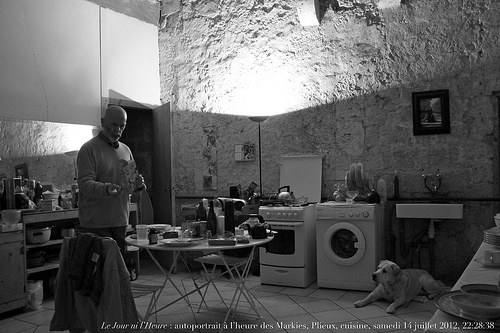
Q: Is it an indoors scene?
A: Yes, it is indoors.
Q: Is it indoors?
A: Yes, it is indoors.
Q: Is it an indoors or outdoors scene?
A: It is indoors.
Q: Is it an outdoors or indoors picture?
A: It is indoors.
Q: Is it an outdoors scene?
A: No, it is indoors.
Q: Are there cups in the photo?
A: No, there are no cups.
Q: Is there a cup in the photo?
A: No, there are no cups.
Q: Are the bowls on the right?
A: Yes, the bowls are on the right of the image.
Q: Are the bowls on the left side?
A: No, the bowls are on the right of the image.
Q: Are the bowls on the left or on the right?
A: The bowls are on the right of the image.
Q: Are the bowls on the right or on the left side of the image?
A: The bowls are on the right of the image.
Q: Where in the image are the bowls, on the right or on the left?
A: The bowls are on the right of the image.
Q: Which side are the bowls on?
A: The bowls are on the right of the image.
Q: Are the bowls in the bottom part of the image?
A: Yes, the bowls are in the bottom of the image.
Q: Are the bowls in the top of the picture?
A: No, the bowls are in the bottom of the image.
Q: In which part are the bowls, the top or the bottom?
A: The bowls are in the bottom of the image.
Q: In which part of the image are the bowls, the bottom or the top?
A: The bowls are in the bottom of the image.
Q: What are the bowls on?
A: The bowls are on the counter top.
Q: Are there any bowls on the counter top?
A: Yes, there are bowls on the counter top.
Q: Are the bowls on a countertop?
A: Yes, the bowls are on a countertop.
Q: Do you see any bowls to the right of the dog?
A: Yes, there are bowls to the right of the dog.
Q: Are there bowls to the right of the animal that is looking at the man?
A: Yes, there are bowls to the right of the dog.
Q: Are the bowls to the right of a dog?
A: Yes, the bowls are to the right of a dog.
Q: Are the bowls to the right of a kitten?
A: No, the bowls are to the right of a dog.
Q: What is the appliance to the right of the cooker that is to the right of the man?
A: The appliance is a washing machine.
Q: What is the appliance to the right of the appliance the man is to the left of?
A: The appliance is a washing machine.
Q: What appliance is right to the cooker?
A: The appliance is a washing machine.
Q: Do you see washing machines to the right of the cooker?
A: Yes, there is a washing machine to the right of the cooker.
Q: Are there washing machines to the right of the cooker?
A: Yes, there is a washing machine to the right of the cooker.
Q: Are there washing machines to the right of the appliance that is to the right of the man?
A: Yes, there is a washing machine to the right of the cooker.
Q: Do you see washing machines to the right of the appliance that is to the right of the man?
A: Yes, there is a washing machine to the right of the cooker.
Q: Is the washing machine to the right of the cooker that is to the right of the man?
A: Yes, the washing machine is to the right of the cooker.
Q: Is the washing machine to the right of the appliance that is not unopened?
A: Yes, the washing machine is to the right of the cooker.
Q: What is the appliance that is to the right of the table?
A: The appliance is a washing machine.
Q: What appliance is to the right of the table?
A: The appliance is a washing machine.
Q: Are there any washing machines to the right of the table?
A: Yes, there is a washing machine to the right of the table.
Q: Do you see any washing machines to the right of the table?
A: Yes, there is a washing machine to the right of the table.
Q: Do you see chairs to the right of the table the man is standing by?
A: No, there is a washing machine to the right of the table.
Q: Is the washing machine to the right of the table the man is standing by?
A: Yes, the washing machine is to the right of the table.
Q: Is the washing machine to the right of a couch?
A: No, the washing machine is to the right of the table.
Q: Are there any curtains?
A: No, there are no curtains.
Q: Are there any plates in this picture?
A: Yes, there is a plate.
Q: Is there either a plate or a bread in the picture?
A: Yes, there is a plate.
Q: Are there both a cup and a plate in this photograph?
A: No, there is a plate but no cups.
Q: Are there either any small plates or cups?
A: Yes, there is a small plate.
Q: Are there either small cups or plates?
A: Yes, there is a small plate.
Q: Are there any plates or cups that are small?
A: Yes, the plate is small.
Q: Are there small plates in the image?
A: Yes, there is a small plate.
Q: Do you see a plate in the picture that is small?
A: Yes, there is a plate that is small.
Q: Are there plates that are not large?
A: Yes, there is a small plate.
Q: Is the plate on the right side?
A: Yes, the plate is on the right of the image.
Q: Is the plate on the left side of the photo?
A: No, the plate is on the right of the image.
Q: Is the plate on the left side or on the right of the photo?
A: The plate is on the right of the image.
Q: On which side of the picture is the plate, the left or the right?
A: The plate is on the right of the image.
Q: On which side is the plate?
A: The plate is on the right of the image.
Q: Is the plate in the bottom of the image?
A: Yes, the plate is in the bottom of the image.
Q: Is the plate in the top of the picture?
A: No, the plate is in the bottom of the image.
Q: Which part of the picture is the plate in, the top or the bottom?
A: The plate is in the bottom of the image.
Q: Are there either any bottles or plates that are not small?
A: No, there is a plate but it is small.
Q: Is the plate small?
A: Yes, the plate is small.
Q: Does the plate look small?
A: Yes, the plate is small.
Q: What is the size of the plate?
A: The plate is small.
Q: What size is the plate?
A: The plate is small.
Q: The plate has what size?
A: The plate is small.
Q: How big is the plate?
A: The plate is small.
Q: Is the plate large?
A: No, the plate is small.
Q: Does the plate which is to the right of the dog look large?
A: No, the plate is small.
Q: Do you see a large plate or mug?
A: No, there is a plate but it is small.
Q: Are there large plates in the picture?
A: No, there is a plate but it is small.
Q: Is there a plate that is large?
A: No, there is a plate but it is small.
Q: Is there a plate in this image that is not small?
A: No, there is a plate but it is small.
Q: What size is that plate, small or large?
A: The plate is small.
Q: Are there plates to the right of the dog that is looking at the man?
A: Yes, there is a plate to the right of the dog.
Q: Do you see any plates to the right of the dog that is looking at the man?
A: Yes, there is a plate to the right of the dog.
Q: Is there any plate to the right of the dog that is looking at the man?
A: Yes, there is a plate to the right of the dog.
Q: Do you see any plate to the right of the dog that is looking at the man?
A: Yes, there is a plate to the right of the dog.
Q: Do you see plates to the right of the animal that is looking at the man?
A: Yes, there is a plate to the right of the dog.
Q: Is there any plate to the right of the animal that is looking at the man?
A: Yes, there is a plate to the right of the dog.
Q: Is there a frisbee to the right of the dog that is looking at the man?
A: No, there is a plate to the right of the dog.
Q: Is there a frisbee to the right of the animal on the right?
A: No, there is a plate to the right of the dog.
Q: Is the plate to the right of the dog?
A: Yes, the plate is to the right of the dog.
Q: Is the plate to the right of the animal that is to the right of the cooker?
A: Yes, the plate is to the right of the dog.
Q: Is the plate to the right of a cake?
A: No, the plate is to the right of the dog.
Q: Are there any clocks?
A: No, there are no clocks.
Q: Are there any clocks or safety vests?
A: No, there are no clocks or safety vests.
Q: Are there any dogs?
A: Yes, there is a dog.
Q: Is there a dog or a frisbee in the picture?
A: Yes, there is a dog.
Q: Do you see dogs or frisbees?
A: Yes, there is a dog.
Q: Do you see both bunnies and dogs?
A: No, there is a dog but no bunnies.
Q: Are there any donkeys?
A: No, there are no donkeys.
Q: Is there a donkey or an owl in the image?
A: No, there are no donkeys or owls.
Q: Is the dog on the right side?
A: Yes, the dog is on the right of the image.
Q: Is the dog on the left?
A: No, the dog is on the right of the image.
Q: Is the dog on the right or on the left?
A: The dog is on the right of the image.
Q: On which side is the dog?
A: The dog is on the right of the image.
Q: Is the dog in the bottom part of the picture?
A: Yes, the dog is in the bottom of the image.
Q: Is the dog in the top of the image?
A: No, the dog is in the bottom of the image.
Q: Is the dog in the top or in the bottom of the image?
A: The dog is in the bottom of the image.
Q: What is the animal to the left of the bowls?
A: The animal is a dog.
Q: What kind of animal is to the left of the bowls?
A: The animal is a dog.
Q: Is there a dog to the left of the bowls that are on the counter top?
A: Yes, there is a dog to the left of the bowls.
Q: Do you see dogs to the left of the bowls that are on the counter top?
A: Yes, there is a dog to the left of the bowls.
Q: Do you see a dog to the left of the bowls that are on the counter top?
A: Yes, there is a dog to the left of the bowls.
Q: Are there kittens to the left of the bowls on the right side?
A: No, there is a dog to the left of the bowls.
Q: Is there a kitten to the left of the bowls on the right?
A: No, there is a dog to the left of the bowls.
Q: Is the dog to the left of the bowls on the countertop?
A: Yes, the dog is to the left of the bowls.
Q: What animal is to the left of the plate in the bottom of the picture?
A: The animal is a dog.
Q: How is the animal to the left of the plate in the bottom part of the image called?
A: The animal is a dog.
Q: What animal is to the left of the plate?
A: The animal is a dog.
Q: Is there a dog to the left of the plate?
A: Yes, there is a dog to the left of the plate.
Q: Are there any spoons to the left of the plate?
A: No, there is a dog to the left of the plate.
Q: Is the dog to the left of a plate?
A: Yes, the dog is to the left of a plate.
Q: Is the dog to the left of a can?
A: No, the dog is to the left of a plate.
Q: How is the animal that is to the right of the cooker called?
A: The animal is a dog.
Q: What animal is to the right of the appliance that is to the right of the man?
A: The animal is a dog.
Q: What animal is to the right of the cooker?
A: The animal is a dog.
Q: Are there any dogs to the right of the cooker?
A: Yes, there is a dog to the right of the cooker.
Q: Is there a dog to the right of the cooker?
A: Yes, there is a dog to the right of the cooker.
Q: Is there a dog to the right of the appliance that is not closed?
A: Yes, there is a dog to the right of the cooker.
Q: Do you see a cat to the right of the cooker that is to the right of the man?
A: No, there is a dog to the right of the cooker.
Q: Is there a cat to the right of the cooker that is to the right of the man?
A: No, there is a dog to the right of the cooker.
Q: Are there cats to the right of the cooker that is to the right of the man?
A: No, there is a dog to the right of the cooker.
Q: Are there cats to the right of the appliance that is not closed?
A: No, there is a dog to the right of the cooker.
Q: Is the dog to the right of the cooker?
A: Yes, the dog is to the right of the cooker.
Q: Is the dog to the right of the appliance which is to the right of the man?
A: Yes, the dog is to the right of the cooker.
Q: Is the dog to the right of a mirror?
A: No, the dog is to the right of the cooker.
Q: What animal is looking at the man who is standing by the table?
A: The dog is looking at the man.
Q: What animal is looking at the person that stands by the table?
A: The dog is looking at the man.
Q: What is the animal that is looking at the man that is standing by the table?
A: The animal is a dog.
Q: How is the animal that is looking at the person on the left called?
A: The animal is a dog.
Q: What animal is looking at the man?
A: The animal is a dog.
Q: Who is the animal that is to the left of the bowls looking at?
A: The dog is looking at the man.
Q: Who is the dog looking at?
A: The dog is looking at the man.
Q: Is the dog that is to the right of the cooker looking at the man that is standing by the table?
A: Yes, the dog is looking at the man.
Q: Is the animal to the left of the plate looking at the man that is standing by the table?
A: Yes, the dog is looking at the man.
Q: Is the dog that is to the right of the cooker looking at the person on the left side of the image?
A: Yes, the dog is looking at the man.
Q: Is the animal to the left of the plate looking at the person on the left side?
A: Yes, the dog is looking at the man.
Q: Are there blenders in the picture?
A: No, there are no blenders.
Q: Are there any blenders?
A: No, there are no blenders.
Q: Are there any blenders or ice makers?
A: No, there are no blenders or ice makers.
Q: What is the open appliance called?
A: The appliance is a cooker.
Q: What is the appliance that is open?
A: The appliance is a cooker.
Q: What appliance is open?
A: The appliance is a cooker.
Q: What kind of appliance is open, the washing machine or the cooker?
A: The cooker is open.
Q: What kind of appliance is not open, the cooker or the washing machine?
A: The washing machine is not open.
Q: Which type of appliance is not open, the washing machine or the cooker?
A: The washing machine is not open.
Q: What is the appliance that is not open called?
A: The appliance is a washing machine.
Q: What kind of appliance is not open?
A: The appliance is a washing machine.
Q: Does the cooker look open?
A: Yes, the cooker is open.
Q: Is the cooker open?
A: Yes, the cooker is open.